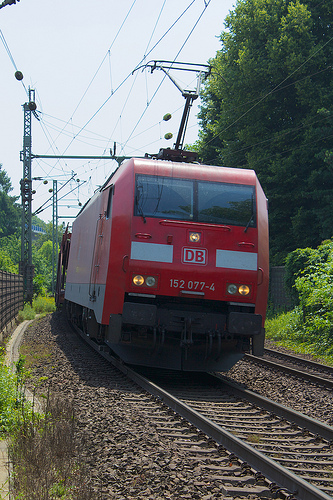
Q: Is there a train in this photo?
A: Yes, there is a train.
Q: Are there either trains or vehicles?
A: Yes, there is a train.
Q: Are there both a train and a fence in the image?
A: Yes, there are both a train and a fence.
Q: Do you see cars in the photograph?
A: No, there are no cars.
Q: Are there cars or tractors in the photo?
A: No, there are no cars or tractors.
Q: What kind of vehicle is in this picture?
A: The vehicle is a train.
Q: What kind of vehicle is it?
A: The vehicle is a train.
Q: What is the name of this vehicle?
A: This is a train.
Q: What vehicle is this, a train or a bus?
A: This is a train.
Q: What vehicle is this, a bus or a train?
A: This is a train.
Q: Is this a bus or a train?
A: This is a train.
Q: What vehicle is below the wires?
A: The vehicle is a train.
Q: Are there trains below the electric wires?
A: Yes, there is a train below the wires.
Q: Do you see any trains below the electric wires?
A: Yes, there is a train below the wires.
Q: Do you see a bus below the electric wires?
A: No, there is a train below the wires.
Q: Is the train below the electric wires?
A: Yes, the train is below the wires.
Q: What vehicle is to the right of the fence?
A: The vehicle is a train.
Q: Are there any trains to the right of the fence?
A: Yes, there is a train to the right of the fence.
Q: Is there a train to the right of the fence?
A: Yes, there is a train to the right of the fence.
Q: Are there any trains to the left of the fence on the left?
A: No, the train is to the right of the fence.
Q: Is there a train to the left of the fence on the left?
A: No, the train is to the right of the fence.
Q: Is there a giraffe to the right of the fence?
A: No, there is a train to the right of the fence.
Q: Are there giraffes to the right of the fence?
A: No, there is a train to the right of the fence.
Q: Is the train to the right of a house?
A: No, the train is to the right of a fence.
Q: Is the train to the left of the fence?
A: No, the train is to the right of the fence.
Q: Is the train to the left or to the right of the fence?
A: The train is to the right of the fence.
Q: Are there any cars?
A: No, there are no cars.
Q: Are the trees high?
A: Yes, the trees are high.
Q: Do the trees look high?
A: Yes, the trees are high.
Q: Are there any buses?
A: No, there are no buses.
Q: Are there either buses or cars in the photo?
A: No, there are no buses or cars.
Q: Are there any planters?
A: No, there are no planters.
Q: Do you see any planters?
A: No, there are no planters.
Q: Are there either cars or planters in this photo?
A: No, there are no planters or cars.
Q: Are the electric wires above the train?
A: Yes, the wires are above the train.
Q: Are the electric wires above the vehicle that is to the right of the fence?
A: Yes, the wires are above the train.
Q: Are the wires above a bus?
A: No, the wires are above the train.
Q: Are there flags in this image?
A: No, there are no flags.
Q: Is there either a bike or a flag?
A: No, there are no flags or bikes.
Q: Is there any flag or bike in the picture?
A: No, there are no flags or bikes.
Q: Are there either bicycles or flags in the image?
A: No, there are no flags or bicycles.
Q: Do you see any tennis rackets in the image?
A: No, there are no tennis rackets.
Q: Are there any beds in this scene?
A: Yes, there is a bed.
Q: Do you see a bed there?
A: Yes, there is a bed.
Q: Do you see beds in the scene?
A: Yes, there is a bed.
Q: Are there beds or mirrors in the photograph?
A: Yes, there is a bed.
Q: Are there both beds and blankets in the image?
A: No, there is a bed but no blankets.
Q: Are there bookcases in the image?
A: No, there are no bookcases.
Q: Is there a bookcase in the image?
A: No, there are no bookcases.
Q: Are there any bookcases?
A: No, there are no bookcases.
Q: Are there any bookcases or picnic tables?
A: No, there are no bookcases or picnic tables.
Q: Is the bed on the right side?
A: Yes, the bed is on the right of the image.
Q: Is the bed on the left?
A: No, the bed is on the right of the image.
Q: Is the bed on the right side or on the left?
A: The bed is on the right of the image.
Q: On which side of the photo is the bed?
A: The bed is on the right of the image.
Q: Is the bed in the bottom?
A: Yes, the bed is in the bottom of the image.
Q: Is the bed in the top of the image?
A: No, the bed is in the bottom of the image.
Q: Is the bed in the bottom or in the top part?
A: The bed is in the bottom of the image.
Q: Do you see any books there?
A: No, there are no books.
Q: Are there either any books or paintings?
A: No, there are no books or paintings.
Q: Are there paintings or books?
A: No, there are no books or paintings.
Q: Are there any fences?
A: Yes, there is a fence.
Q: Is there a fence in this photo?
A: Yes, there is a fence.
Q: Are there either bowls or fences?
A: Yes, there is a fence.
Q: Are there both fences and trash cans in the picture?
A: No, there is a fence but no trash cans.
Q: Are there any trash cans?
A: No, there are no trash cans.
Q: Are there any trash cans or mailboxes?
A: No, there are no trash cans or mailboxes.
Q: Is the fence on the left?
A: Yes, the fence is on the left of the image.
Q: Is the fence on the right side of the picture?
A: No, the fence is on the left of the image.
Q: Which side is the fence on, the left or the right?
A: The fence is on the left of the image.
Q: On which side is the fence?
A: The fence is on the left of the image.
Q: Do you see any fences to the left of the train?
A: Yes, there is a fence to the left of the train.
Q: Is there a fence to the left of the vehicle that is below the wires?
A: Yes, there is a fence to the left of the train.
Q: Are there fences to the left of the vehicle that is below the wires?
A: Yes, there is a fence to the left of the train.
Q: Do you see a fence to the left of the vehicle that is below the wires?
A: Yes, there is a fence to the left of the train.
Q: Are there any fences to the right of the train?
A: No, the fence is to the left of the train.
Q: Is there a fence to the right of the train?
A: No, the fence is to the left of the train.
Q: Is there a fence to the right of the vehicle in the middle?
A: No, the fence is to the left of the train.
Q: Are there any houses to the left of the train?
A: No, there is a fence to the left of the train.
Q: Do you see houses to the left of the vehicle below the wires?
A: No, there is a fence to the left of the train.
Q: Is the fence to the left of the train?
A: Yes, the fence is to the left of the train.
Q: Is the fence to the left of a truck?
A: No, the fence is to the left of the train.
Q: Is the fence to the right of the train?
A: No, the fence is to the left of the train.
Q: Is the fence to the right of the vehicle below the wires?
A: No, the fence is to the left of the train.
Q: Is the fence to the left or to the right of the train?
A: The fence is to the left of the train.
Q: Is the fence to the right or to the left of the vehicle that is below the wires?
A: The fence is to the left of the train.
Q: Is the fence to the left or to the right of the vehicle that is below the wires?
A: The fence is to the left of the train.